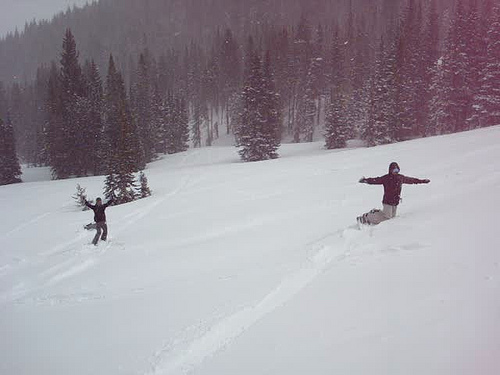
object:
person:
[353, 162, 428, 226]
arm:
[364, 173, 386, 184]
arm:
[402, 175, 424, 185]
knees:
[380, 211, 394, 220]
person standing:
[78, 195, 118, 246]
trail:
[151, 224, 371, 373]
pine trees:
[226, 31, 283, 161]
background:
[0, 0, 500, 374]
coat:
[82, 199, 115, 224]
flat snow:
[0, 123, 500, 374]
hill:
[0, 0, 500, 374]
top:
[63, 27, 77, 60]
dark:
[0, 0, 95, 38]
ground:
[0, 123, 500, 374]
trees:
[321, 24, 356, 149]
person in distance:
[80, 194, 114, 244]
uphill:
[80, 189, 119, 246]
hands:
[83, 203, 89, 205]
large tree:
[95, 51, 150, 204]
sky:
[0, 0, 99, 39]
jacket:
[365, 162, 423, 206]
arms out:
[366, 172, 424, 186]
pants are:
[356, 204, 397, 223]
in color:
[356, 203, 399, 224]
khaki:
[96, 223, 101, 237]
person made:
[161, 206, 386, 374]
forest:
[0, 0, 500, 187]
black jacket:
[361, 162, 429, 206]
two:
[78, 160, 429, 247]